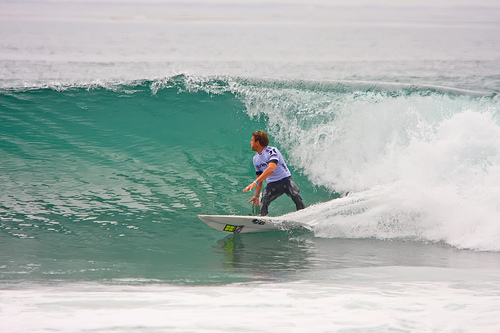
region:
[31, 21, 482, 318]
the ocean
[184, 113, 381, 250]
a surfer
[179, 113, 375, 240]
a man on a surfboard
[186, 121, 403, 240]
a man surfing in the ocean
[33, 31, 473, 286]
a large wave on the ocean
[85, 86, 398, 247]
a surfer looks at the wave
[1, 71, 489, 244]
a surfer riding a wave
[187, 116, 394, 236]
a man surfs in the ocean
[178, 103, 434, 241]
a man rides a white surfboard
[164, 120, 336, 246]
The man is surfing.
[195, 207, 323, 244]
The surfboard is white.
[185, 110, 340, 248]
The man rides a wave.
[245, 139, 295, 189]
The man's shirt is blue.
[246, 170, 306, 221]
The man's pants are black.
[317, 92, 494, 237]
The wave is white.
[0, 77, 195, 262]
The water is green.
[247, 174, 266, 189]
The man wears a watch.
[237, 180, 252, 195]
The man wears a ring.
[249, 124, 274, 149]
The man has brown hair.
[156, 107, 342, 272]
man is surfing medium wave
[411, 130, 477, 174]
part of a water splash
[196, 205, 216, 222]
tip of a swimming board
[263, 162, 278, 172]
part of an elbow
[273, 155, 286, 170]
part of a top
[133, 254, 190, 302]
part of a water body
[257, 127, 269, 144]
hair of a man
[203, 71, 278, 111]
edge of the curve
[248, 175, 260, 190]
part of a band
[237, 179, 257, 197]
part of a left hand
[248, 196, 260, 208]
part of a right hand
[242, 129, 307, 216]
Man in a blue shirt surfing on a surf board.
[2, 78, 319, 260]
Inside of a large green and blue wave a man is surfing in front of.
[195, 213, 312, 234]
A white surf board in the water.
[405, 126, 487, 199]
White water coming out from behind a white surfboard.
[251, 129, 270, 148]
Brown hair on a man surfing in the ocean.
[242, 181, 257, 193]
Left hand of a man surfing in the ocean.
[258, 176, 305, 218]
Black wet suit pants on a man surfing.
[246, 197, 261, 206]
Right hand on a man surfing in the ocean.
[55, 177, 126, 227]
Ripples in the green and white water.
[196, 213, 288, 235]
White surfboard in the water.